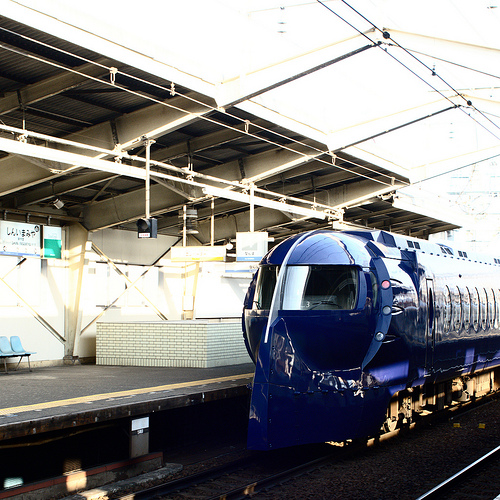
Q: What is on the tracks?
A: A train.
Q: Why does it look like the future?
A: Prototype.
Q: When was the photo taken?
A: Daytime.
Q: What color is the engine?
A: Blue.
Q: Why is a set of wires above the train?
A: Electricity for train.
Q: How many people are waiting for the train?
A: None.